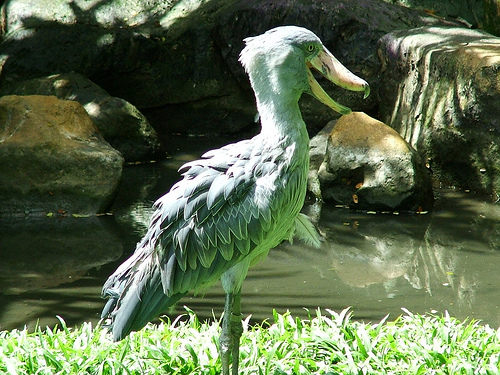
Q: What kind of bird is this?
A: Shoebill.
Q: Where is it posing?
A: By a creek.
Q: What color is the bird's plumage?
A: Gray.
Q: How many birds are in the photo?
A: 1.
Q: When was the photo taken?
A: Daytime.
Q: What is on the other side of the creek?
A: Rocks.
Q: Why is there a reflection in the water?
A: Water is still.